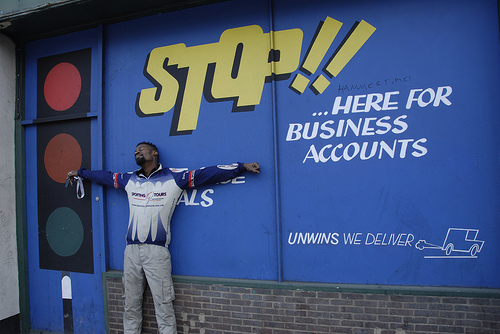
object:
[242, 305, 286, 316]
brick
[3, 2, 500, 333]
wall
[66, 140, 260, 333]
man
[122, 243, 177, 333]
pants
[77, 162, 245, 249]
shirt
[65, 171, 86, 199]
key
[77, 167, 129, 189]
arm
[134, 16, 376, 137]
word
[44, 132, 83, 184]
stoplight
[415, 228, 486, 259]
truck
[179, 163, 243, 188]
arms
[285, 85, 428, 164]
sign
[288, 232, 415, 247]
sign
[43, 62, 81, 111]
circle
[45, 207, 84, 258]
circle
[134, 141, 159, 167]
head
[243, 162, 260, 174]
hand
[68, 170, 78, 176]
hand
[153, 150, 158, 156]
ear